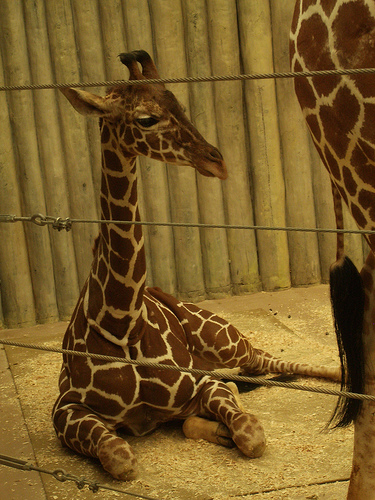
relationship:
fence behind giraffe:
[0, 0, 375, 329] [51, 59, 316, 463]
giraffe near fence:
[51, 49, 348, 479] [0, 0, 375, 329]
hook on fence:
[29, 209, 72, 237] [17, 58, 370, 143]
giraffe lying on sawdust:
[51, 59, 316, 463] [161, 444, 327, 478]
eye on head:
[122, 115, 158, 136] [72, 84, 220, 185]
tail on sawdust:
[208, 356, 289, 410] [161, 444, 327, 478]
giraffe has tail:
[278, 7, 368, 196] [334, 90, 366, 431]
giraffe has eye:
[51, 59, 316, 463] [122, 115, 158, 136]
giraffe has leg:
[51, 59, 316, 463] [168, 382, 275, 469]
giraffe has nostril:
[51, 59, 316, 463] [206, 148, 234, 165]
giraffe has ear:
[51, 59, 316, 463] [53, 83, 107, 137]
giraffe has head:
[51, 59, 316, 463] [72, 84, 220, 185]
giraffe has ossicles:
[51, 59, 316, 463] [117, 34, 169, 75]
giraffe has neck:
[51, 59, 316, 463] [90, 110, 143, 237]